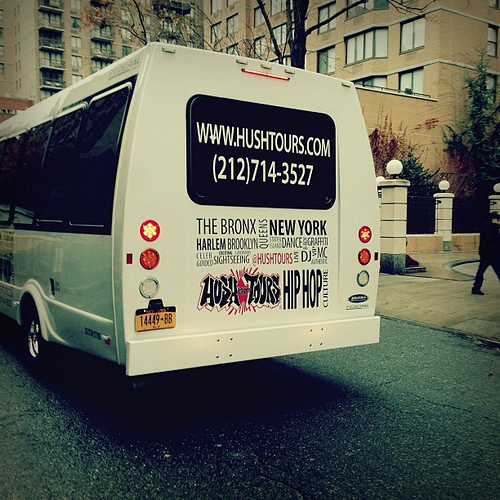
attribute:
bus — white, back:
[102, 41, 403, 386]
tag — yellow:
[126, 286, 182, 334]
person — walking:
[468, 212, 498, 292]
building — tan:
[25, 9, 118, 72]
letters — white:
[185, 102, 326, 205]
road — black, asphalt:
[224, 429, 342, 481]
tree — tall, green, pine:
[434, 76, 492, 206]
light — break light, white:
[135, 269, 171, 301]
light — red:
[132, 240, 170, 272]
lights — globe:
[382, 138, 415, 175]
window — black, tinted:
[37, 105, 119, 229]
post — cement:
[368, 175, 434, 281]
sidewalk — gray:
[387, 256, 452, 338]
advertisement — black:
[188, 118, 340, 189]